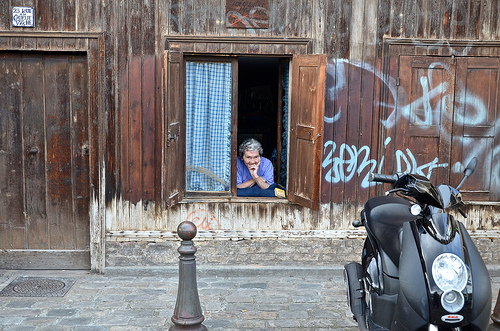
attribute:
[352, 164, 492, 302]
vehicle — black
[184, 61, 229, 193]
curtain — checkered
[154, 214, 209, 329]
post — metal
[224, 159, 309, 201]
shirt — blue 